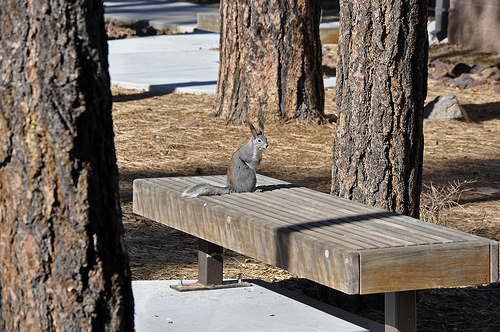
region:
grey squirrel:
[170, 117, 279, 213]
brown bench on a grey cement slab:
[127, 162, 495, 318]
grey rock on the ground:
[420, 85, 470, 126]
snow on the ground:
[80, 20, 227, 118]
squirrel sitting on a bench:
[126, 118, 496, 316]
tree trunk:
[311, 0, 432, 222]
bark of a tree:
[346, 32, 411, 179]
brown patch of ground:
[115, 95, 207, 156]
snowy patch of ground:
[117, 20, 212, 102]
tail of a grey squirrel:
[176, 177, 225, 209]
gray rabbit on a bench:
[179, 115, 279, 202]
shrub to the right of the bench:
[421, 177, 481, 222]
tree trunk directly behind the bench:
[336, 0, 429, 228]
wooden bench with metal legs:
[126, 162, 499, 317]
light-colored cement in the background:
[117, 35, 217, 93]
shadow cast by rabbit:
[252, 160, 327, 199]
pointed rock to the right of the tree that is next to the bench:
[424, 90, 474, 131]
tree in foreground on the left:
[4, 1, 136, 325]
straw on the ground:
[140, 112, 217, 152]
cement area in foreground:
[154, 302, 300, 329]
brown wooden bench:
[130, 173, 495, 287]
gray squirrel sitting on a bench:
[185, 122, 266, 197]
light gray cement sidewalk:
[110, 32, 215, 97]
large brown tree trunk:
[216, 20, 331, 126]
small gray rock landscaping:
[427, 90, 468, 126]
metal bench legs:
[175, 230, 251, 291]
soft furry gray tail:
[180, 180, 230, 195]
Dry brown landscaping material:
[123, 106, 203, 161]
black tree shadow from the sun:
[115, 76, 211, 107]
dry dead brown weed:
[423, 173, 480, 227]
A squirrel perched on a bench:
[189, 121, 278, 211]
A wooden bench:
[153, 176, 493, 298]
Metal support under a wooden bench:
[182, 223, 232, 295]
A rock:
[426, 78, 471, 131]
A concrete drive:
[107, 25, 307, 105]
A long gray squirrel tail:
[180, 178, 233, 206]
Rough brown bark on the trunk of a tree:
[333, 2, 415, 181]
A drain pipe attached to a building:
[425, 2, 460, 45]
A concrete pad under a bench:
[128, 274, 316, 324]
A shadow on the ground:
[114, 65, 214, 117]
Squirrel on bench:
[179, 108, 277, 207]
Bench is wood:
[125, 154, 498, 303]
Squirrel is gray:
[179, 119, 271, 204]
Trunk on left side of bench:
[2, 4, 141, 329]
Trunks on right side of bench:
[276, 0, 438, 205]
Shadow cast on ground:
[119, 66, 215, 116]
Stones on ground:
[424, 48, 495, 125]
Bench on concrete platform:
[139, 267, 395, 329]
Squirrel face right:
[179, 116, 272, 199]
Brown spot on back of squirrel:
[220, 139, 241, 187]